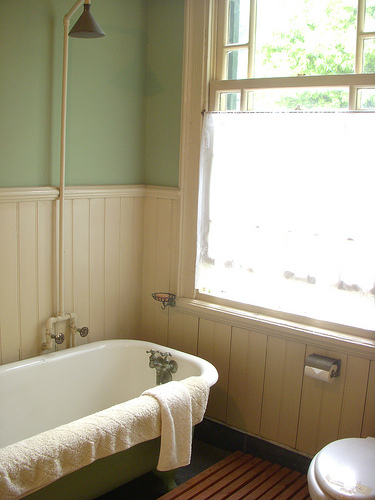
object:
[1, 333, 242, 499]
tub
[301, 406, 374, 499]
toilet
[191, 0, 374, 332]
window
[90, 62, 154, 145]
wall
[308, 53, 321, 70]
leaves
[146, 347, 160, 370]
faucets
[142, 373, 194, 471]
towel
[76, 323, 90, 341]
handles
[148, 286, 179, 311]
dish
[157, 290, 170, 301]
soap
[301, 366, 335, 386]
paper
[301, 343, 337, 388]
paper roll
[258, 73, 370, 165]
sunshine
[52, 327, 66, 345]
knobs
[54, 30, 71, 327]
pipe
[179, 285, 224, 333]
sill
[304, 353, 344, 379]
holder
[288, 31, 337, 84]
tree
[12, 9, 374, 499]
bathroom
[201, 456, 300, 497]
pallet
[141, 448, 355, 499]
floor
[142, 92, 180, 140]
walls